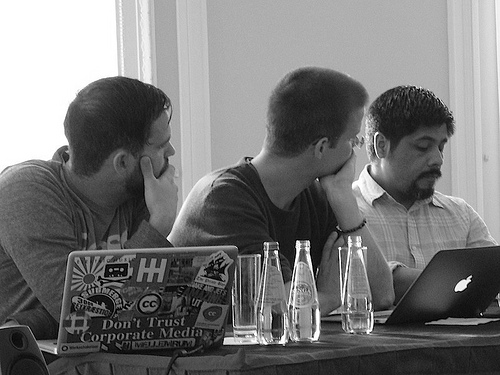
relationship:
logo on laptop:
[455, 273, 476, 292] [322, 244, 498, 325]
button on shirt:
[411, 243, 418, 252] [351, 164, 500, 314]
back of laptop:
[57, 245, 240, 362] [35, 245, 241, 358]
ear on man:
[374, 134, 392, 160] [353, 86, 499, 308]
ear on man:
[112, 152, 131, 183] [3, 76, 181, 337]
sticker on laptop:
[96, 260, 133, 293] [35, 245, 241, 358]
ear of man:
[374, 134, 392, 160] [353, 86, 499, 308]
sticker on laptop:
[137, 293, 162, 314] [35, 245, 241, 358]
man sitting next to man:
[353, 86, 499, 308] [168, 67, 395, 325]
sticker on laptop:
[192, 301, 229, 330] [35, 245, 241, 358]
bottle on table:
[256, 240, 291, 344] [36, 321, 498, 374]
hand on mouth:
[139, 156, 178, 229] [160, 157, 171, 173]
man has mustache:
[353, 86, 499, 308] [415, 166, 444, 180]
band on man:
[335, 219, 366, 233] [168, 67, 395, 325]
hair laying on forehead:
[167, 99, 175, 130] [149, 108, 171, 148]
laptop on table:
[322, 244, 498, 325] [36, 321, 498, 374]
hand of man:
[319, 149, 357, 194] [168, 67, 395, 325]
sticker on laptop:
[194, 248, 235, 290] [35, 245, 241, 358]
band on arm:
[335, 219, 366, 234] [316, 146, 394, 312]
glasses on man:
[311, 136, 362, 154] [168, 67, 395, 325]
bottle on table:
[287, 240, 324, 344] [36, 321, 498, 374]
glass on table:
[231, 252, 265, 343] [36, 321, 498, 374]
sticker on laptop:
[61, 310, 94, 336] [35, 245, 241, 358]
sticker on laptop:
[68, 316, 211, 343] [35, 245, 241, 358]